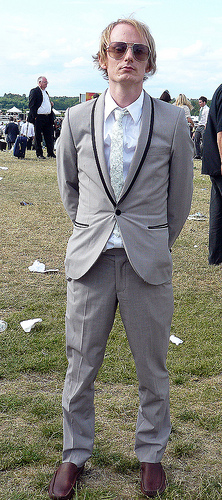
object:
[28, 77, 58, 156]
man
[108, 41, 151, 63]
glasses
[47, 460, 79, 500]
shoe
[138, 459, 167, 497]
shoe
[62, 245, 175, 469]
pants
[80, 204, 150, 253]
midsection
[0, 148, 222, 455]
grass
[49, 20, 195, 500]
man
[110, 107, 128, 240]
tie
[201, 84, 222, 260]
people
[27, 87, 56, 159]
suit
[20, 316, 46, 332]
garbage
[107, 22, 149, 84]
face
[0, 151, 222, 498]
ground